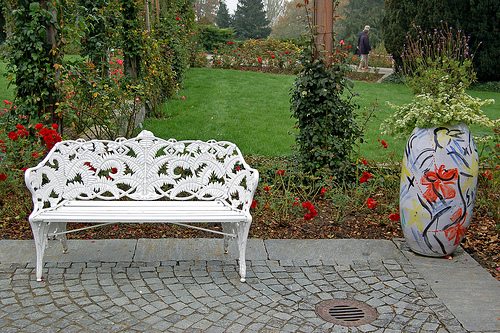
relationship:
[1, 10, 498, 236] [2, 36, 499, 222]
garden with flowers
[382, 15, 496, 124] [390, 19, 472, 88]
plant with flowers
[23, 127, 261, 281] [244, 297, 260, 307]
bench on bricks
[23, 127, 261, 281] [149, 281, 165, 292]
bench on bricks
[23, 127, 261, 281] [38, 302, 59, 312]
bench on bricks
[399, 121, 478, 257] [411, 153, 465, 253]
flower pot with print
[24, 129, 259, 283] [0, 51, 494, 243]
bench behind garden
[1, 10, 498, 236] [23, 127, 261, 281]
garden behind bench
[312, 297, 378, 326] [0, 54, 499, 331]
drainage hole on ground